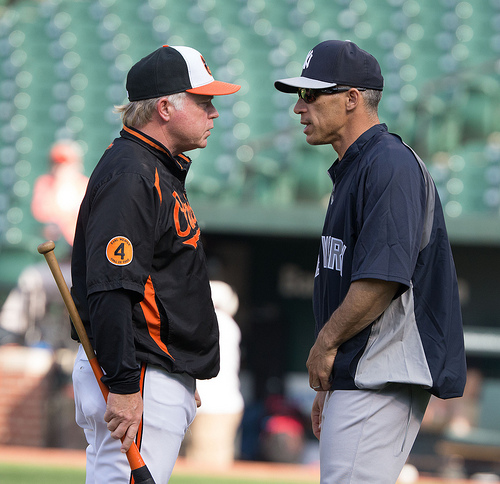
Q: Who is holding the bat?
A: The man in black.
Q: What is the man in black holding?
A: A bat.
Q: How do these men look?
A: Serious.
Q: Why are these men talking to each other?
A: They seem to be meeting.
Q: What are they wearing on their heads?
A: Hats.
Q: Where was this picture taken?
A: In a ball park.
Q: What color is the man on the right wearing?
A: Blue.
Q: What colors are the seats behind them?
A: Green.